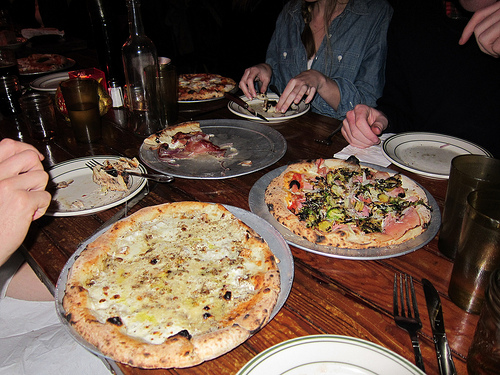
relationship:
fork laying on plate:
[85, 156, 175, 184] [38, 152, 148, 217]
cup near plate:
[56, 78, 106, 146] [38, 152, 148, 217]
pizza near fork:
[49, 197, 275, 370] [85, 156, 175, 184]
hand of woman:
[278, 65, 325, 113] [233, 2, 389, 121]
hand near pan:
[278, 65, 325, 113] [137, 115, 290, 183]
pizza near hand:
[49, 197, 275, 370] [278, 65, 325, 113]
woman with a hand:
[233, 2, 389, 121] [278, 65, 325, 113]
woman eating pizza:
[233, 2, 389, 121] [255, 91, 284, 111]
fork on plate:
[85, 156, 175, 184] [38, 152, 148, 217]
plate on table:
[38, 152, 148, 217] [4, 35, 496, 370]